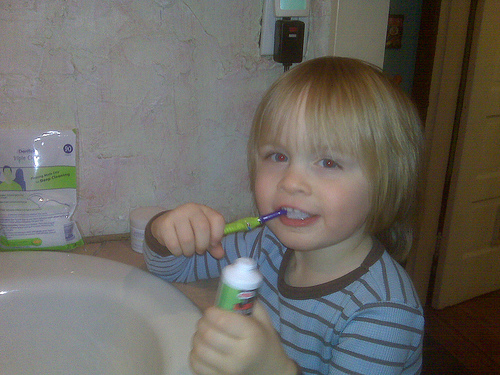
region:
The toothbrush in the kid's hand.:
[217, 210, 285, 230]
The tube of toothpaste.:
[220, 253, 260, 312]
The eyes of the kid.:
[263, 143, 350, 170]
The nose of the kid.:
[275, 168, 311, 196]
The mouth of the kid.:
[266, 200, 329, 232]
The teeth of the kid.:
[282, 204, 307, 221]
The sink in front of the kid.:
[4, 245, 216, 371]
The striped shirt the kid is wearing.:
[162, 202, 424, 374]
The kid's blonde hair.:
[259, 63, 419, 244]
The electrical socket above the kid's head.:
[268, 1, 305, 63]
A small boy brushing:
[246, 69, 421, 366]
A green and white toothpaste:
[217, 256, 261, 313]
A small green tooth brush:
[215, 201, 288, 241]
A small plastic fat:
[128, 209, 149, 248]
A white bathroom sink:
[7, 258, 115, 363]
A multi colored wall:
[95, 70, 200, 165]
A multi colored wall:
[5, 47, 75, 113]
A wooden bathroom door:
[440, 116, 479, 309]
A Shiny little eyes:
[258, 141, 347, 173]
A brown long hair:
[313, 75, 419, 227]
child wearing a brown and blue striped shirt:
[244, 60, 401, 370]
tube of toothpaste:
[218, 251, 261, 318]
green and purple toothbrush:
[223, 210, 286, 243]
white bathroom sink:
[2, 275, 139, 372]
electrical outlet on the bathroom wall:
[273, 1, 307, 64]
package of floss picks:
[0, 128, 77, 248]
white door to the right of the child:
[441, 7, 496, 293]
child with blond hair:
[248, 56, 408, 254]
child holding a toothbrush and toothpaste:
[143, 57, 410, 368]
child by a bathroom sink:
[146, 55, 417, 374]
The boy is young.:
[164, 57, 418, 373]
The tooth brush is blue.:
[219, 203, 288, 249]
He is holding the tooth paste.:
[195, 252, 270, 330]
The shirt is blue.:
[135, 182, 399, 372]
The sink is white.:
[3, 253, 200, 373]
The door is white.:
[439, 5, 499, 336]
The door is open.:
[445, 1, 496, 302]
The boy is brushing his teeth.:
[143, 66, 430, 373]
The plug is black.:
[271, 20, 299, 66]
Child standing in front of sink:
[139, 54, 449, 374]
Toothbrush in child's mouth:
[195, 187, 317, 242]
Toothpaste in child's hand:
[203, 257, 277, 339]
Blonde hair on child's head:
[245, 43, 425, 262]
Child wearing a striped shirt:
[155, 57, 448, 364]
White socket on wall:
[259, 0, 356, 68]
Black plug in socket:
[262, 15, 309, 67]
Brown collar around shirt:
[269, 240, 387, 300]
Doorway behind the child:
[407, 2, 498, 323]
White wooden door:
[429, 10, 497, 306]